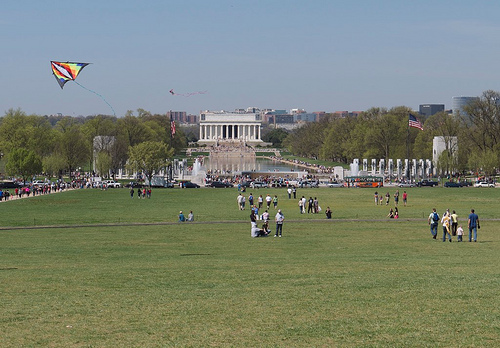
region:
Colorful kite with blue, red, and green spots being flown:
[32, 38, 87, 91]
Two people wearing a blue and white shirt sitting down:
[170, 205, 207, 227]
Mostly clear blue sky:
[109, 9, 471, 69]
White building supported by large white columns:
[192, 109, 268, 142]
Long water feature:
[195, 154, 282, 171]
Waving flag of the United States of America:
[400, 102, 431, 128]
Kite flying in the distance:
[160, 85, 214, 97]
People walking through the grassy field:
[219, 191, 492, 276]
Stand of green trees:
[8, 124, 171, 165]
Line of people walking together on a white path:
[10, 176, 88, 198]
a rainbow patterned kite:
[33, 36, 168, 170]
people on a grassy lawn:
[194, 174, 380, 281]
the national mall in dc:
[134, 74, 373, 244]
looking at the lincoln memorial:
[156, 91, 334, 196]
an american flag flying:
[373, 99, 428, 151]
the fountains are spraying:
[166, 79, 324, 218]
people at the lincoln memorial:
[159, 96, 313, 236]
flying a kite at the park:
[39, 47, 210, 250]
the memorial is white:
[179, 73, 319, 228]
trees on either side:
[131, 71, 326, 230]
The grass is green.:
[117, 251, 409, 341]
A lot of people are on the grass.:
[204, 190, 498, 258]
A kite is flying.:
[43, 49, 107, 93]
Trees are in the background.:
[324, 113, 404, 148]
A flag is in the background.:
[403, 105, 432, 140]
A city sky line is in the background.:
[266, 102, 366, 131]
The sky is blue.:
[120, 12, 263, 69]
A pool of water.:
[156, 150, 313, 190]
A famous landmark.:
[187, 98, 281, 156]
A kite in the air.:
[45, 54, 117, 114]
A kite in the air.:
[164, 87, 213, 99]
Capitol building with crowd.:
[188, 111, 271, 164]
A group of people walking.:
[426, 205, 484, 245]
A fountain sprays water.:
[188, 157, 203, 178]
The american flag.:
[408, 112, 424, 130]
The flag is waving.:
[405, 110, 427, 130]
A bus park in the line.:
[341, 175, 383, 188]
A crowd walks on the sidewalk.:
[0, 180, 76, 202]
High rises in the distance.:
[162, 95, 482, 123]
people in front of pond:
[169, 149, 372, 204]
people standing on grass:
[228, 181, 313, 272]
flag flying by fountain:
[359, 99, 445, 179]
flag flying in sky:
[22, 44, 137, 138]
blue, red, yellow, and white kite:
[47, 53, 118, 93]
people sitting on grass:
[164, 197, 229, 243]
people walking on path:
[7, 179, 94, 202]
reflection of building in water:
[184, 136, 294, 202]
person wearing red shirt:
[393, 180, 421, 216]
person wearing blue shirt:
[461, 201, 491, 255]